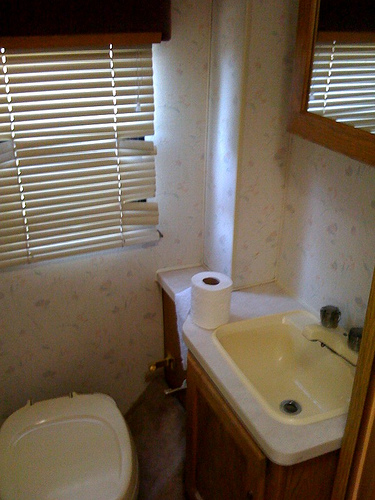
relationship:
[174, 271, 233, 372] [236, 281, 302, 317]
paper on counter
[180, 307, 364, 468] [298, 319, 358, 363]
sink and faucet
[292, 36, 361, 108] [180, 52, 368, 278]
mirror on wall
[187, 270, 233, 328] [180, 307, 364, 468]
paper on sink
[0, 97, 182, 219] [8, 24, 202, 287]
blinds on a window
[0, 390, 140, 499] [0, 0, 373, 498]
toilet bowl in bathroom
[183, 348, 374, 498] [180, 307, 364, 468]
cabinet under sink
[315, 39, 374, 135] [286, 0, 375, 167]
reflection in mirror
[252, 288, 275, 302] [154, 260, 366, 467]
part of counter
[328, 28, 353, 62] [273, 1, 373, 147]
part of mirror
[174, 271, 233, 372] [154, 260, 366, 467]
paper on counter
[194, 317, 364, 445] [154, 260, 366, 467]
sink in counter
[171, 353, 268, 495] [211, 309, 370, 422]
door under sink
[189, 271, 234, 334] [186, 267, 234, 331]
roll of toilet paper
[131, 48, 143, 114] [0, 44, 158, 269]
string of blinds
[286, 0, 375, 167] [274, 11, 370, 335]
mirror mounted on wall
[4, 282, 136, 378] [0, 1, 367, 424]
wallpaper on wall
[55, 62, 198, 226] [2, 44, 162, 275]
sunlight shing through window